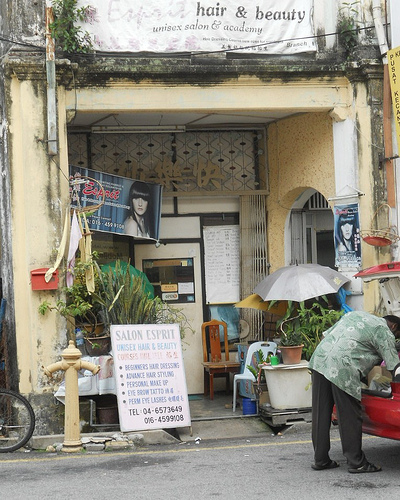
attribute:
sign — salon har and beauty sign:
[100, 315, 215, 438]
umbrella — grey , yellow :
[231, 291, 301, 321]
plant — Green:
[279, 299, 339, 356]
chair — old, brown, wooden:
[196, 318, 239, 406]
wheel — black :
[47, 159, 117, 217]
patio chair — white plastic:
[229, 341, 280, 412]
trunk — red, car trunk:
[315, 377, 396, 442]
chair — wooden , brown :
[197, 317, 244, 398]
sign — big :
[73, 165, 163, 242]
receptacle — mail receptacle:
[30, 268, 59, 291]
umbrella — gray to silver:
[265, 266, 330, 302]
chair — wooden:
[193, 314, 238, 400]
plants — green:
[38, 250, 196, 349]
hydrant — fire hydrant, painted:
[45, 337, 115, 451]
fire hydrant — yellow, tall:
[41, 336, 105, 457]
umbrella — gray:
[255, 261, 348, 302]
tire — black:
[0, 389, 36, 452]